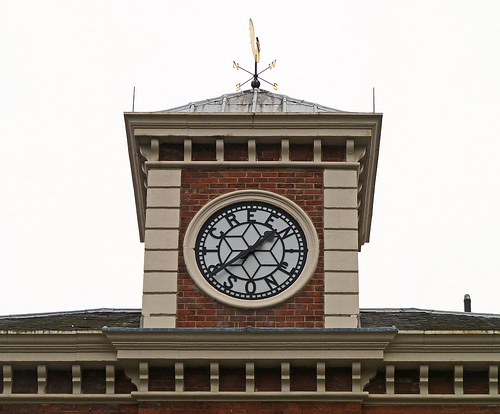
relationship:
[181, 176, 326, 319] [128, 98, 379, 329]
clock in tower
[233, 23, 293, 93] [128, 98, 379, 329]
weather vane on tower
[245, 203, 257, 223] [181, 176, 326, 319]
letter e on clock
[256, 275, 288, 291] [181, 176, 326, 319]
letter on clock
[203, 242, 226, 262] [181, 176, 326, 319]
letter on clock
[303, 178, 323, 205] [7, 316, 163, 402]
bricks on building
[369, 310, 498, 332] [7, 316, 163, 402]
roof of building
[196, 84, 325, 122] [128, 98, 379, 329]
pyramid on tower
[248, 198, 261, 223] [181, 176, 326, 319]
letter e on clock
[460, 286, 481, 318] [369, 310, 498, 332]
exhaust vent on roof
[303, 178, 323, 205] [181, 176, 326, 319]
bricks behind clock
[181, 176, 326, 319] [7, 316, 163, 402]
clock on building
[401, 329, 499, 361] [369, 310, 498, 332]
decorative accent on roof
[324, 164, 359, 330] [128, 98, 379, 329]
shingles on tower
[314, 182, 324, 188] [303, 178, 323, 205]
part of bricks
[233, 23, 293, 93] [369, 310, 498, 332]
weather vane on roof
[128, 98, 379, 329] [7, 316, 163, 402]
tower on building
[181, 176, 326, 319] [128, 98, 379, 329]
clock on tower